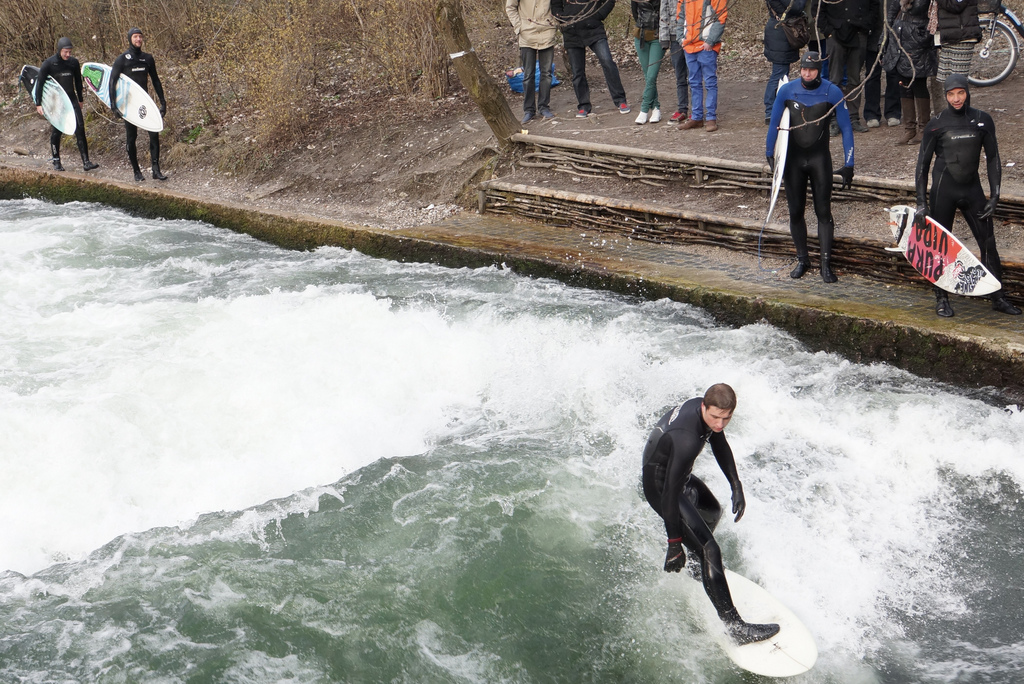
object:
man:
[643, 383, 782, 647]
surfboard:
[19, 64, 76, 135]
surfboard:
[80, 61, 163, 132]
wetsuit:
[766, 51, 856, 283]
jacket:
[674, 0, 724, 55]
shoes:
[633, 106, 661, 125]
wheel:
[967, 19, 1021, 87]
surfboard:
[882, 204, 1002, 296]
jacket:
[504, 0, 561, 51]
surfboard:
[677, 550, 820, 678]